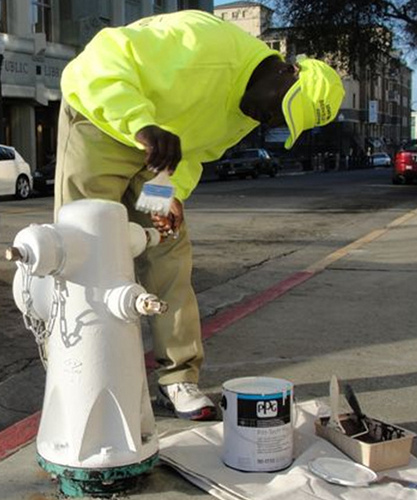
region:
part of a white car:
[1, 142, 40, 202]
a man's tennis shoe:
[151, 383, 218, 420]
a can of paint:
[212, 377, 299, 479]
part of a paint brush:
[328, 372, 341, 429]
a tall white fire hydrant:
[4, 191, 181, 493]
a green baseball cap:
[278, 52, 345, 154]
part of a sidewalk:
[0, 204, 415, 498]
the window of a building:
[31, 3, 44, 36]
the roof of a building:
[216, 0, 259, 10]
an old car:
[210, 145, 280, 181]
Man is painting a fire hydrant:
[3, 5, 348, 494]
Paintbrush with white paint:
[121, 156, 182, 228]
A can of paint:
[210, 369, 304, 480]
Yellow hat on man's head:
[254, 42, 351, 158]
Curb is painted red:
[5, 270, 313, 461]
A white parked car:
[0, 136, 34, 203]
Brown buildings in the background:
[215, 2, 411, 155]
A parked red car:
[390, 132, 415, 182]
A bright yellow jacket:
[55, 5, 281, 205]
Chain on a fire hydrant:
[16, 245, 75, 351]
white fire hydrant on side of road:
[4, 198, 166, 495]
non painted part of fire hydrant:
[37, 452, 161, 495]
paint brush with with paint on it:
[135, 168, 175, 215]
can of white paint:
[223, 376, 292, 466]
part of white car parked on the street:
[0, 144, 32, 199]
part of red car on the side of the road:
[391, 139, 416, 181]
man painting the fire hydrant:
[54, 10, 345, 421]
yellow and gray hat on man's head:
[285, 57, 344, 149]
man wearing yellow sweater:
[52, 9, 346, 421]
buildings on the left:
[0, 0, 412, 193]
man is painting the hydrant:
[0, 0, 403, 430]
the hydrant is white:
[2, 185, 189, 479]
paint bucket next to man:
[219, 361, 304, 481]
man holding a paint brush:
[122, 113, 191, 243]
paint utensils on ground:
[300, 354, 411, 468]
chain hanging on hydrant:
[10, 264, 79, 359]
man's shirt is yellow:
[31, 1, 257, 216]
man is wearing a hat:
[277, 44, 341, 155]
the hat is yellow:
[269, 35, 347, 153]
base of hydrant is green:
[24, 440, 160, 498]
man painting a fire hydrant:
[3, 9, 346, 498]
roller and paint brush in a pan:
[313, 373, 416, 472]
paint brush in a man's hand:
[134, 159, 179, 216]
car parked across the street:
[214, 144, 283, 182]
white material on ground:
[158, 382, 413, 499]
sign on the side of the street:
[367, 99, 379, 124]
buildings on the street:
[0, 2, 412, 193]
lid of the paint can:
[307, 454, 377, 487]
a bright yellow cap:
[280, 56, 347, 148]